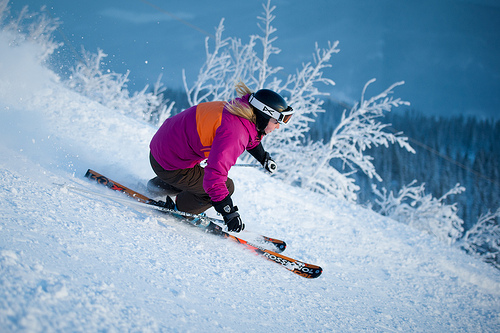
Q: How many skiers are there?
A: One.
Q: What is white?
A: Snow.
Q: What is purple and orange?
A: Skiier's jacket.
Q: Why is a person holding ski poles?
A: To ski.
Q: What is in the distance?
A: Trees.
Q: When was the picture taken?
A: Daytime.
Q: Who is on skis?
A: A woman.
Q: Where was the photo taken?
A: On a ski slope.